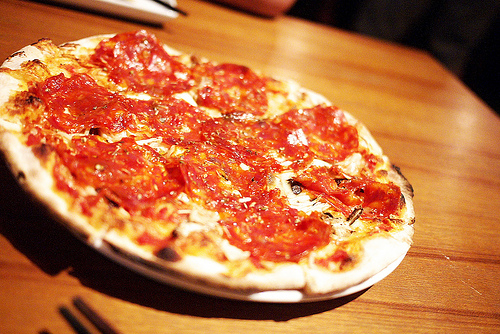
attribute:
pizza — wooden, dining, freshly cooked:
[7, 26, 423, 304]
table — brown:
[6, 37, 451, 327]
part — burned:
[315, 238, 410, 285]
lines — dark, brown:
[425, 239, 495, 310]